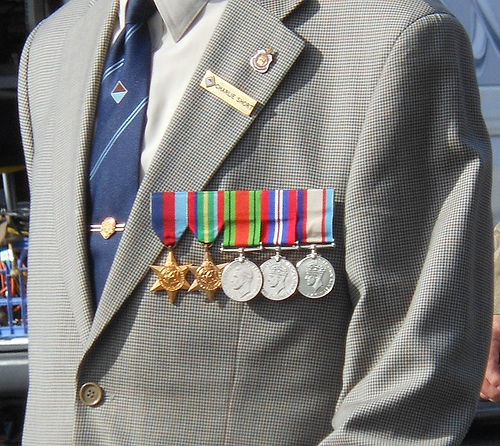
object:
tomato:
[442, 394, 499, 445]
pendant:
[148, 244, 336, 304]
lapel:
[73, 0, 312, 381]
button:
[79, 382, 102, 405]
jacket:
[18, 0, 495, 443]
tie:
[84, 0, 154, 321]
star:
[148, 244, 230, 304]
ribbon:
[150, 187, 335, 247]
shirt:
[108, 0, 231, 187]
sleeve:
[320, 14, 495, 446]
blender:
[0, 163, 31, 339]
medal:
[148, 188, 335, 303]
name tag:
[198, 70, 258, 118]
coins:
[221, 249, 337, 302]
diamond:
[85, 216, 126, 240]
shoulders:
[15, 0, 478, 83]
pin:
[249, 48, 271, 74]